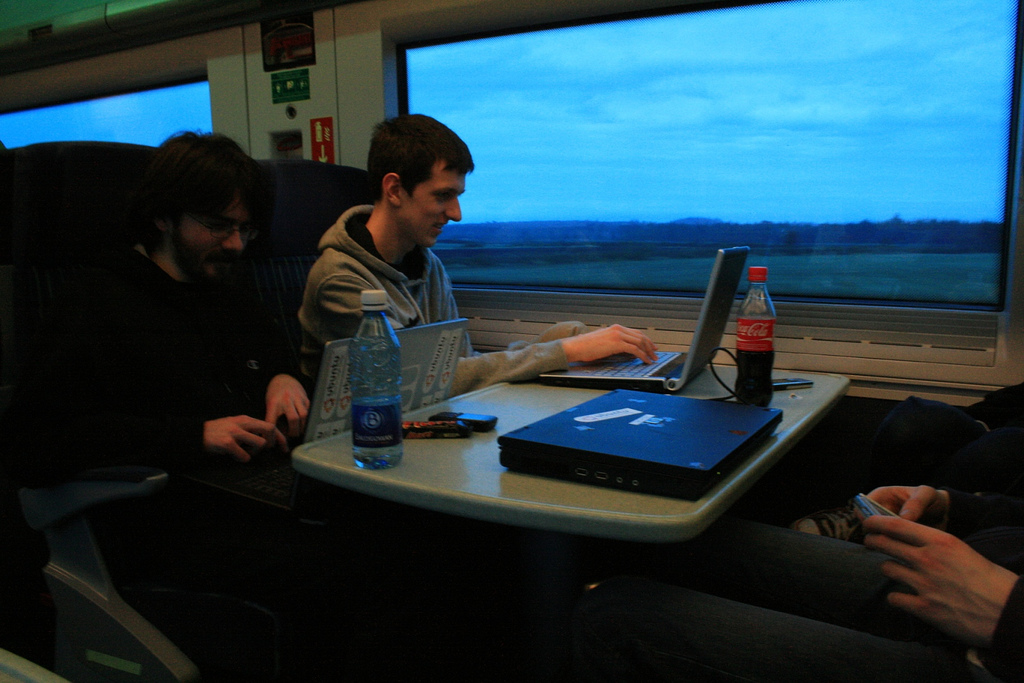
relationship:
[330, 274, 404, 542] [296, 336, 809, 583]
bottle of water on table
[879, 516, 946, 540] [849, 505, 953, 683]
finger on hand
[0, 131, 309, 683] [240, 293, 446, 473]
man using laptop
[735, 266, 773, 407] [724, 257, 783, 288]
bottle with lid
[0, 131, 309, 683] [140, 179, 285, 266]
man wearing glasses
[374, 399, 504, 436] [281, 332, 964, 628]
cell phone on a table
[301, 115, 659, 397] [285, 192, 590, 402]
man wearing sweatshirt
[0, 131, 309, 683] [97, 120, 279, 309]
man with hair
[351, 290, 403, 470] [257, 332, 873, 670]
bottle on a table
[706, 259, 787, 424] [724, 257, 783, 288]
bottle with lid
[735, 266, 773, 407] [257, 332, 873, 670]
bottle on a table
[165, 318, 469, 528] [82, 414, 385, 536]
lap in lap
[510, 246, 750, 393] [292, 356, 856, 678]
laptop on a table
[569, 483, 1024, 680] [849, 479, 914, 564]
man holding cell phone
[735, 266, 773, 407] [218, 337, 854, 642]
bottle on table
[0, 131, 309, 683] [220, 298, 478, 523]
man typing on laptop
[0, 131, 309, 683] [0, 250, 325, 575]
man wearing sweatshirt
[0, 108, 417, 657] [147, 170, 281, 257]
man wearing glasses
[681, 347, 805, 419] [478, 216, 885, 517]
cords going to laptop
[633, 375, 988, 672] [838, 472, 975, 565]
man playing with cellphone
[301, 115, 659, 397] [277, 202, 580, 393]
man wearing sweatshirt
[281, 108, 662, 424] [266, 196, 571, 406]
man wearing sweatshirt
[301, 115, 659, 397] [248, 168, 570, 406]
man wearing sweatshirt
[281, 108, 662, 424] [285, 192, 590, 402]
man wearing sweatshirt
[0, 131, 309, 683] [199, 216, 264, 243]
man wearing glasses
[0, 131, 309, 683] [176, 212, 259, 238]
man wearing glasses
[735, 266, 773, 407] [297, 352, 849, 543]
bottle on table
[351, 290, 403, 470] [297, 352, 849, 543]
bottle on table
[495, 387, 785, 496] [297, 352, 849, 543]
computer on table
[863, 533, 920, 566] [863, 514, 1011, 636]
finger on hand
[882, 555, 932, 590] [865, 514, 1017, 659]
finger on hand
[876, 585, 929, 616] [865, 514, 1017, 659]
finger on hand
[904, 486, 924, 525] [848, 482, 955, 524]
finger on hand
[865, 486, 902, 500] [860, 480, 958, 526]
finger on hand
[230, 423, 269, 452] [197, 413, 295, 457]
finger on hand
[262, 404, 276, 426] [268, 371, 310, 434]
finger on hand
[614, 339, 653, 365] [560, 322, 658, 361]
finger on hand